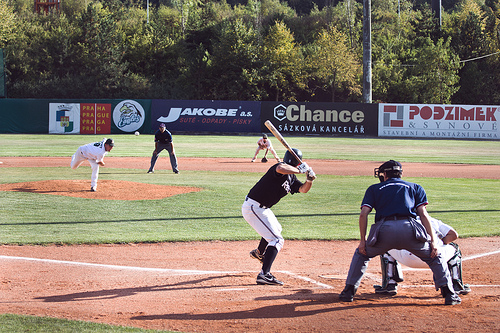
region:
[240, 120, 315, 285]
a baseball player at bat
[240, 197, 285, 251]
a pair of white pants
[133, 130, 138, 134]
a white baseball in mid flight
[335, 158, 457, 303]
a baseball umpire crouching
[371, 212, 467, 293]
a baseball catcher crouching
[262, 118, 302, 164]
a light brown bat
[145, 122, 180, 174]
a person standing in field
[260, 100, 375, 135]
a stadium promotional advertisement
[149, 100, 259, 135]
a stadium promotional advertisement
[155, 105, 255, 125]
White letters on sign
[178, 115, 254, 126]
Red letters on sign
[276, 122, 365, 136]
White letters on sign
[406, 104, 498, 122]
Red letters on sign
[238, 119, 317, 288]
Baseball player holding baseball bat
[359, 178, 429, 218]
Blue and white shirt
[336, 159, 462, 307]
Man wearing blue and white shirt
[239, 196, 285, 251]
White and black pants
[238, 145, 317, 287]
Baseball player wearing white and black pants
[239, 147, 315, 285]
Baseball player wearing black socks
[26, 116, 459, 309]
Players are playing baseball.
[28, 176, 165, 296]
Ground is green and brown color.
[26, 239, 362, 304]
White lines in ground.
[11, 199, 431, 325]
Shadow falls on ground.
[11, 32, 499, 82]
Trees are behind the barrier.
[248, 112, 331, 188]
Bat is brown color.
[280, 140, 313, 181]
Batter helmet is black color.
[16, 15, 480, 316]
Day time picture.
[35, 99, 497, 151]
Letters are in barrier.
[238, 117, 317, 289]
Baseball player waiting for a ball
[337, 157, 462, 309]
Umpire behind home plate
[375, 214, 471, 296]
Baseball catcher in a white uniform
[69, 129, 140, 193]
Pitcher with a baseball flying through the air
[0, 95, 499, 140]
Fence coverd in advertising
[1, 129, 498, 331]
Green and brown baseball field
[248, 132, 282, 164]
Baseball player at second base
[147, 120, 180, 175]
Man in dark clothes standing with hand on knees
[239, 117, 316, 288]
Man holding baseball bat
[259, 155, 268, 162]
Catcher's mit resting on the ground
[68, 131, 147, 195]
A baseball player is throwing a ball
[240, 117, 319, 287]
A baseball player is ready to pitch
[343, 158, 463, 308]
A baseball player squats down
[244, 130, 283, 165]
A baseball player stand in one of the bases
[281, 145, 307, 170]
Baseball player is wearing a helmet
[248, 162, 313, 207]
Baseball player is wearing a black shirt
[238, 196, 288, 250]
Baseball player is wearing white pants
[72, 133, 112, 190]
Baseball player is dressed in all white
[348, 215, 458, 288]
Baseball player is wearing grey pants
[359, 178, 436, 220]
Baseball player is wearing a dark blue shirt.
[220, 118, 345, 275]
batter at the plate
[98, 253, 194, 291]
white line on ground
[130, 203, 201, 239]
grass on the ground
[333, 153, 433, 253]
umpire behind the catcher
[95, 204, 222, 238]
grass in front of the pitcher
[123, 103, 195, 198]
umpire at second base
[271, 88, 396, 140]
advertisement in the outfield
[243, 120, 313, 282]
a man is playing baseball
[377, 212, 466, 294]
a man is playing baseball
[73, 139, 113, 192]
a man is playing baseball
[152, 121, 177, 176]
umpire is bending over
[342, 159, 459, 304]
umpire is bending over